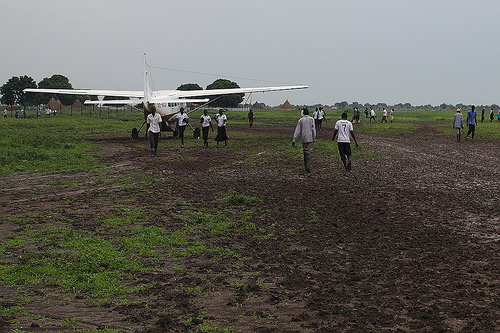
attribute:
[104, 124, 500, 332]
mud — brown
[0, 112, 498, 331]
field — muddy, for landing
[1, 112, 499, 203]
grass — green, short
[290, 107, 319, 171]
man — walking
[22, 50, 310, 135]
plane — white, parked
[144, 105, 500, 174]
people — walking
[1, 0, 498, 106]
sky — gray, cloudy, blue, clear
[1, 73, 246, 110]
trees — green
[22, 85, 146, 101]
wing — white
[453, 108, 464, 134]
outfit — gray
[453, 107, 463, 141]
person — walking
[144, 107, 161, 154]
person — walking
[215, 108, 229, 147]
person — walking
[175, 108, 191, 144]
person — walking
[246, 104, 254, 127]
person — walking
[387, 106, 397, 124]
person — walking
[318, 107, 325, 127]
person — walking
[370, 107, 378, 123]
person — walking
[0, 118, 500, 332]
ground — muddy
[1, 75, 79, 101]
leaves — green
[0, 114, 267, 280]
runway — dirt, weed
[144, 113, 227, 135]
shirts — white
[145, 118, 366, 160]
pants — black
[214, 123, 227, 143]
skirt — black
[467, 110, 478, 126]
shirt — blue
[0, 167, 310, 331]
patches — grassy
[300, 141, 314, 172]
pants — brown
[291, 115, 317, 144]
shirt — long sleeved, gray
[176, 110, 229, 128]
shirts — white